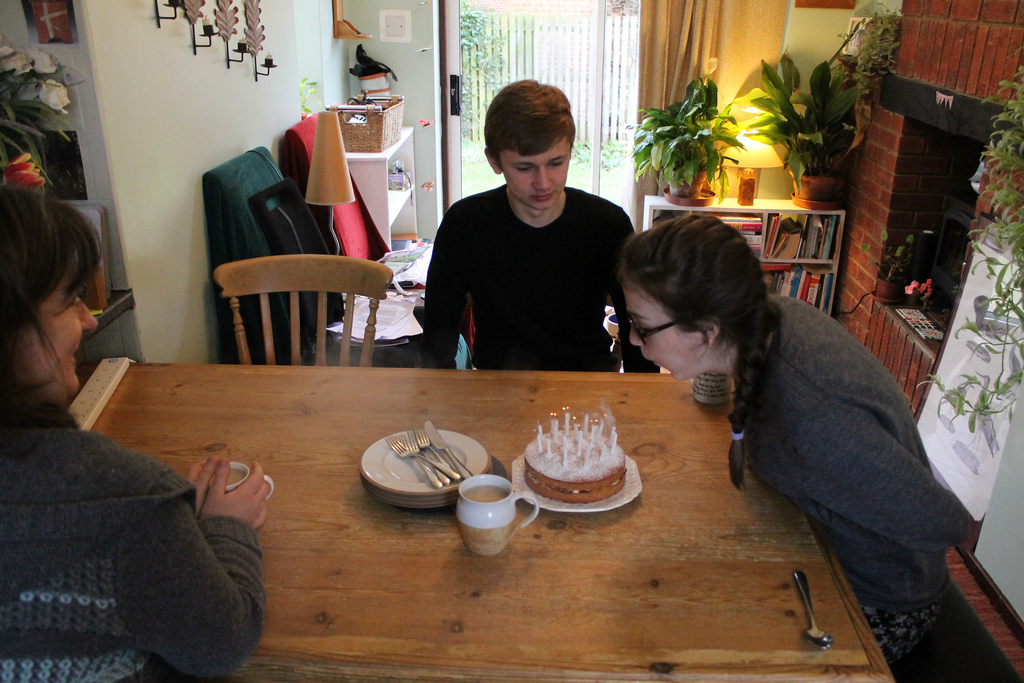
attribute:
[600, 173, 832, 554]
lady — smiling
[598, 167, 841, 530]
lady — blowing out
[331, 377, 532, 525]
plates — white